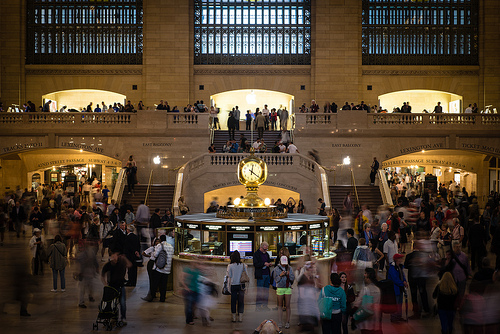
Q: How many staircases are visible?
A: Three.